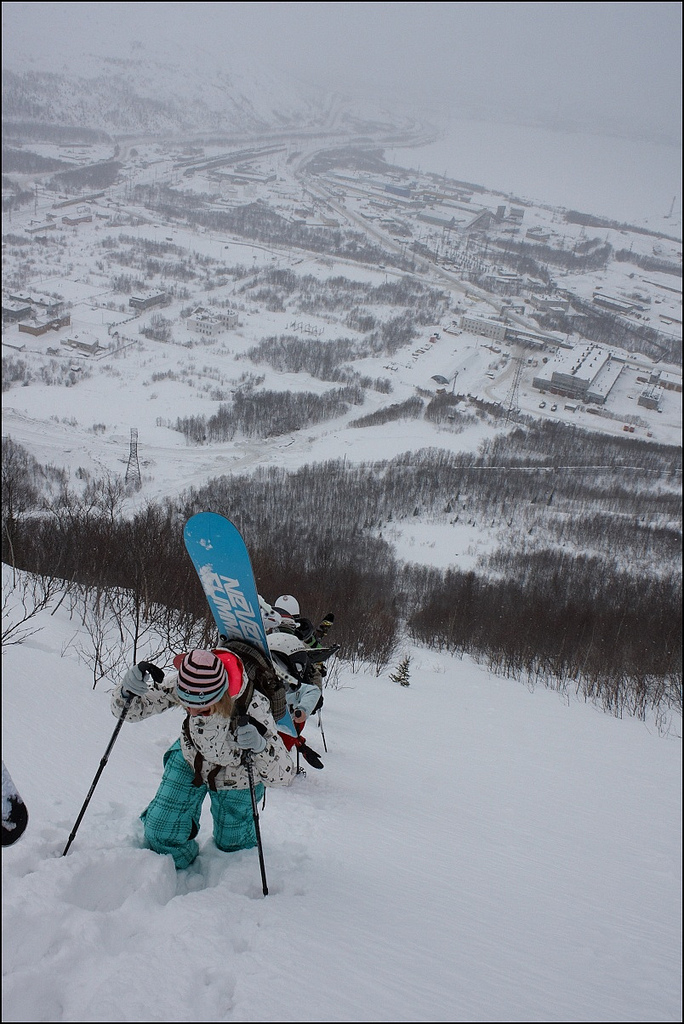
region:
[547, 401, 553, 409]
a car in a parking lot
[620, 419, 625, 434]
a car in a parking lot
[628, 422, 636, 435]
a car in a parking lot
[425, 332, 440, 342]
a car in a parking lot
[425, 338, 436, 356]
a car in a parking lot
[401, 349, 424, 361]
a car in a parking lot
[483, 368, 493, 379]
a car in a parking lot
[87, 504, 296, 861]
Person climbing up hill.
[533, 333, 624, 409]
Top of snow covered building.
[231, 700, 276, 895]
Ski pole in left hand.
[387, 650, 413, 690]
Small pine tree in snow.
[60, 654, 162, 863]
Ski pole in right hand.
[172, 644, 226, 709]
Top of a knitted cap.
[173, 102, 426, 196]
Roads in the distance.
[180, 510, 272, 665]
A blue and white snowboard.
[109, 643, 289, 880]
Woman climbing up a snow-covered mountain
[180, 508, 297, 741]
Snowboard on the woman's back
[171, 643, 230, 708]
Striped beanie on woman's head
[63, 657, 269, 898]
Ski poles in woman's hands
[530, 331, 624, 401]
Building at the bottom of the mountain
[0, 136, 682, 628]
Snow-covered valley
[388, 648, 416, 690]
Tree in the snow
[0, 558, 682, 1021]
Snow-covered mountain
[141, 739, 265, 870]
Plaid snowpants on woman's legs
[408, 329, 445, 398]
Cars in a parking lot at the base of the mountain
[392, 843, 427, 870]
An Asian woman is holding a purse.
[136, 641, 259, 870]
person wearing green plaid pants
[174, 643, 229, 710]
pink and black striped knit hat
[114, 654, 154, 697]
one right gray knit glove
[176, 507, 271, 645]
top curved edge of blue snowboard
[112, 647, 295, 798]
person wearing patterned white coat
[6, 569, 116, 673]
bare tree branches against white snow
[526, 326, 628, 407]
top view of large building covered in snow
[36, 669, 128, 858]
one black thin ski pole against the snow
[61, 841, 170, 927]
large hole in fresh snow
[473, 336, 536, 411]
section of snow covered parking lot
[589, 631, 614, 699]
A shrub in the ground.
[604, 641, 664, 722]
A shrub in the ground.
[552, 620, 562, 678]
A shrub in the ground.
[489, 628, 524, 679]
A shrub in the ground.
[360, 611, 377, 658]
A shrub in the ground.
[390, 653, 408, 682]
A shrub in the ground.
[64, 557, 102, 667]
A shrub in the ground.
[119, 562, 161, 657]
A shrub in the ground.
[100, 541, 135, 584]
A shrub in the ground.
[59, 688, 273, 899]
black ski poles in the snow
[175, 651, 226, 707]
pink and brown striped knit cap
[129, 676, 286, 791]
white jacket the woman is wearing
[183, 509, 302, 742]
blue snowboard with white lettering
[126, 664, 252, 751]
light gray gloves the woman is wearing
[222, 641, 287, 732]
backpack the snowboard is in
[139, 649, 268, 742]
black straps on the ski poles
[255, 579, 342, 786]
second person on the mountainside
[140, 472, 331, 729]
Snow board attached to the back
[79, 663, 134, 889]
Poles for climbing up the side of the hill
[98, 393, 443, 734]
Trees at the bottom of the ravine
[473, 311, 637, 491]
Large building see in the valley below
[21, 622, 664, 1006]
Snow covers the hill as well as the trees below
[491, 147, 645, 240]
Snow covers the body of water below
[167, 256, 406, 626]
Patches of forest seen below the large hill